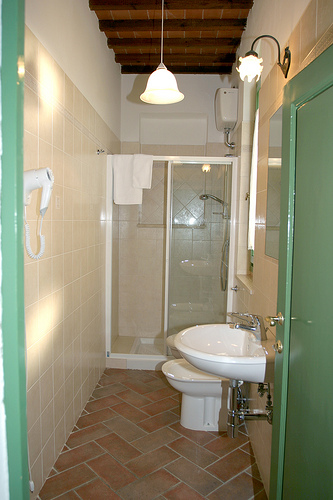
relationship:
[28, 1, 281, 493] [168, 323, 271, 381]
bathroom white sink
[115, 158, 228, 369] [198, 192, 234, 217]
shower metal head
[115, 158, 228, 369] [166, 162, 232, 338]
shower sliding glass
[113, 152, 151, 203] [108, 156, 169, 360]
towels on frame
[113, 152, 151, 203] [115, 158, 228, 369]
towels on shower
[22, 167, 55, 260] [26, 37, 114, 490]
white on wall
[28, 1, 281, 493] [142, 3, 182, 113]
bathroom light fixture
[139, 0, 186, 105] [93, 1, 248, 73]
fixture from roof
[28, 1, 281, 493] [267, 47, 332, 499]
bathroom has green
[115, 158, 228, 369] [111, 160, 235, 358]
shower has glass shower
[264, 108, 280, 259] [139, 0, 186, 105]
mirror under fixture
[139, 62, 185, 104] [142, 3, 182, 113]
white hanging fixture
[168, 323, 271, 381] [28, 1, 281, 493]
sink in bathroom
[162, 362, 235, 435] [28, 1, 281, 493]
toilet in bathroom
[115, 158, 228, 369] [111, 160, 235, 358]
shower with shower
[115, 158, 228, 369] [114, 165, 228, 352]
shower with glass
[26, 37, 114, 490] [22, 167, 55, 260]
wall mounted white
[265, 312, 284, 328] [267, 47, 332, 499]
silver on green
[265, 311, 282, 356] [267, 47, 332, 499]
silver on green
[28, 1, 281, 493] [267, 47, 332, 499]
bathroom green green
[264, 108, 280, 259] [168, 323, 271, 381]
mirror above sink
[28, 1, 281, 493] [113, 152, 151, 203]
bathroom white linens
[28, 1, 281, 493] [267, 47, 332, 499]
bathroom painted green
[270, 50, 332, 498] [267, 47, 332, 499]
green painted green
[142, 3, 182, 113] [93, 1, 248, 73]
light hanging from ceiling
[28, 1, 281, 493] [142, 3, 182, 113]
bathroom ceiling light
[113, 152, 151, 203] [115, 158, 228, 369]
towel draped over shower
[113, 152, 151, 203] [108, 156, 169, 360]
towel draped over frame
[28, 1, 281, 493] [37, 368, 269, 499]
bathroom brown floor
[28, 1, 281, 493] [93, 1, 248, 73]
bathroom wooden ceiling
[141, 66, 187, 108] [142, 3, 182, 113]
white light light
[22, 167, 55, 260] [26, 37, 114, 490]
white mounted to wall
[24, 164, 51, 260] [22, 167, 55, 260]
white hair white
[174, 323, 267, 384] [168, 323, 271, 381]
sink white sink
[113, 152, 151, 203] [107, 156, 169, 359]
towels draped over frame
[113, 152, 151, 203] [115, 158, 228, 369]
towels draped over shower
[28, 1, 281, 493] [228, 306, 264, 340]
bathroom sink faucet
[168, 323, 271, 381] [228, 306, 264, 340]
sink silver faucet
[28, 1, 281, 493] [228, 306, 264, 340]
bathroom silver faucet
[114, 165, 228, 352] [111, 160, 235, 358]
glass sliding shower